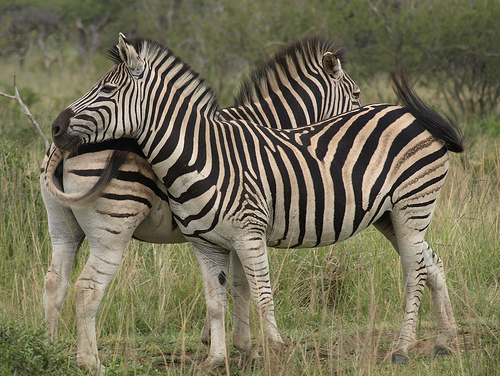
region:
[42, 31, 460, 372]
Zebras standing near each other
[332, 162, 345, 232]
The fur stripe is black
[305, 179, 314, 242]
The fur stripe is white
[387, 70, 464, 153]
The tail is black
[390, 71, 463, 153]
Zebra is swishing its tail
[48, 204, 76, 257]
Leg fur is white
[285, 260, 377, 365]
The brown grass is tall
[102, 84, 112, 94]
The eye is black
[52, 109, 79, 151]
Front of face is black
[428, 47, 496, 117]
Brown bush in the distance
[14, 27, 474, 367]
two zebras crossed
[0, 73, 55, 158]
a stick behind the zebras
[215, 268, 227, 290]
a spot on the zebra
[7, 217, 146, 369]
his legs are thick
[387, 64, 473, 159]
his tail is flicked up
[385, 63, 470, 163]
his tail is brown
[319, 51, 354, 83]
an ear sticking up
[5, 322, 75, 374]
a green plant in front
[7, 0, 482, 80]
trees behind the zebras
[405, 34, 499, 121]
a brown leafless plant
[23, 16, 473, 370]
two zebra's standing in the grass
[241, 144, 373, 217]
striped pattern on zebra fur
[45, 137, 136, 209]
curved black and white zebra tail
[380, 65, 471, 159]
black portion of zebra tail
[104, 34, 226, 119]
black and white zebra mane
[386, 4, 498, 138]
short green tree in field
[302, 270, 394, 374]
patch of yellowed blades of grass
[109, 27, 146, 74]
two pointed zebra ears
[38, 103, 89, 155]
black zebra snout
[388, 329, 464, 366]
two zebra hooves in grass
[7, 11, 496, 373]
two zebras standing next to each other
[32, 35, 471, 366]
two zebras standing outside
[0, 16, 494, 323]
two zebras standing on the grass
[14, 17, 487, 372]
zebras that are standing on the ground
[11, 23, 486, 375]
zebras that are standing on the grass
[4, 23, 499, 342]
zebras in a field together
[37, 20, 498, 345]
two zebras with stripes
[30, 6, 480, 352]
two white zebras with black stripes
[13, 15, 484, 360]
zebras with stripes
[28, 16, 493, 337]
zebras with white stripes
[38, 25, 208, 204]
the head of a zebra.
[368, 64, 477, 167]
a black zebra tail.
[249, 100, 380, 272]
the body of a zebra.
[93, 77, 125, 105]
a left zebra eye.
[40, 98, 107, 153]
the mouth of a zebra.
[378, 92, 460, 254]
the rear end of a zebra.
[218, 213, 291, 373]
front left leg of a zebra.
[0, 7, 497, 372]
a field full of grass.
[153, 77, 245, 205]
a neck of a zebra.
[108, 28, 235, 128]
a black and white zebra mow hawk.